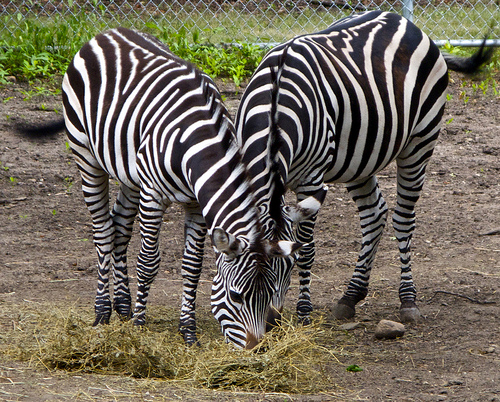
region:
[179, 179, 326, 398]
zebras are eating hay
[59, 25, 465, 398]
two zebras with stripe furs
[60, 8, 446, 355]
Two black and white zebras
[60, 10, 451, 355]
Black and white striped zebras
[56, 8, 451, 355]
Two zebras grazing on grass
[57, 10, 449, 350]
Two zebras eating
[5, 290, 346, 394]
Pile of dry grass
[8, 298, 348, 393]
Pile of light brown hay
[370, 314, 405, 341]
Light brown rock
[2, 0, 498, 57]
Silver metal fence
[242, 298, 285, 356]
Brown noses of zebras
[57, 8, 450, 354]
Two zebras standing in dirt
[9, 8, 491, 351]
two black and white zebras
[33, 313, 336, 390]
pile of hay on the ground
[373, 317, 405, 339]
rock is on the ground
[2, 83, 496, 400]
ground is covered in dirt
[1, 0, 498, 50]
chain link fence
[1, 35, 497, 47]
horizontal support beam for a fence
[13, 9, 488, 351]
two zebras eating hay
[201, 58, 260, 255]
mane on the top of zebras neck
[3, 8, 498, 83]
weeds growing around fence line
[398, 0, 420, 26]
vertical metal fence support beam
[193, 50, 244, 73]
The grass is green.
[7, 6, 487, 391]
Two zebras are eating hay.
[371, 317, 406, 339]
A rock is on the ground.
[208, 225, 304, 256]
The zebra has two ears.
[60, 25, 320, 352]
The zebra has black and white stripes.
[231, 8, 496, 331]
The zebra is standing on dirt.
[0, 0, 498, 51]
Grass is growing behind the fence.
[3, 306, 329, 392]
The hay is yellow.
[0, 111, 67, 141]
The zebra's tail is black.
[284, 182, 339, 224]
The zebra's ear is black and white.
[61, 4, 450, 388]
a couple of zebras eating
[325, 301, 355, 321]
a gray hoof on a zebra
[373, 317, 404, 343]
a brown rock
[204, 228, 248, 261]
the right ear of a zebra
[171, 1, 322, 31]
a silver chain link fence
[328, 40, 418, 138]
black and white strips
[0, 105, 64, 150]
a black tail of a zebra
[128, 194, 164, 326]
front right leg of a zebra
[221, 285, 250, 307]
a eye of a zebra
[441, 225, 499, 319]
dirt and tree limbs